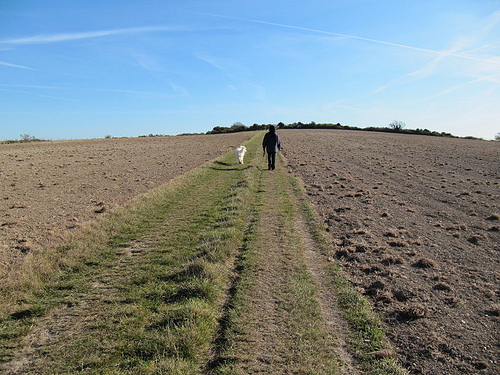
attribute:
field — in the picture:
[288, 132, 489, 369]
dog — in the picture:
[234, 140, 249, 168]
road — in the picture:
[130, 178, 332, 330]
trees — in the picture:
[204, 112, 394, 135]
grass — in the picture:
[130, 245, 216, 334]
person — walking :
[261, 122, 281, 169]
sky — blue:
[2, 4, 499, 126]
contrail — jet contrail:
[249, 20, 490, 82]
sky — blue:
[39, 16, 489, 109]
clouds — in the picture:
[411, 38, 491, 109]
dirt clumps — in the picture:
[376, 207, 468, 310]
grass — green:
[158, 173, 325, 363]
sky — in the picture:
[59, 29, 445, 141]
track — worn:
[186, 165, 358, 370]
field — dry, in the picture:
[5, 131, 497, 373]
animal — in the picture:
[233, 143, 248, 164]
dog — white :
[239, 145, 248, 166]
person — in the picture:
[261, 123, 283, 168]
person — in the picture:
[246, 123, 301, 174]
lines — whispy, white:
[183, 6, 469, 75]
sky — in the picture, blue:
[2, 0, 497, 145]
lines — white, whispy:
[374, 46, 473, 91]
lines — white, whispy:
[2, 19, 234, 44]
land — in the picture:
[9, 144, 483, 341]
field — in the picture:
[38, 127, 275, 348]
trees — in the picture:
[196, 108, 296, 143]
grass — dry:
[141, 169, 254, 373]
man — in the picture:
[258, 124, 284, 173]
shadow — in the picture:
[201, 140, 237, 176]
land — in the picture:
[189, 198, 361, 290]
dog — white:
[230, 139, 247, 172]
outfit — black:
[262, 132, 278, 162]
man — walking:
[261, 125, 283, 172]